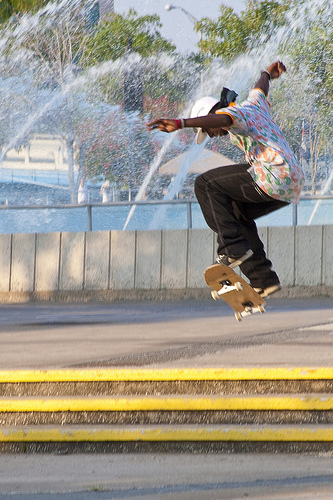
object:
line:
[0, 367, 332, 385]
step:
[0, 365, 333, 398]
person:
[143, 62, 298, 296]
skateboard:
[202, 261, 268, 325]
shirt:
[216, 88, 307, 202]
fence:
[0, 192, 330, 234]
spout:
[118, 0, 332, 233]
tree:
[0, 0, 172, 203]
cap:
[186, 96, 219, 145]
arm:
[178, 112, 237, 133]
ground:
[0, 453, 332, 499]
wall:
[0, 224, 333, 303]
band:
[177, 117, 187, 131]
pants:
[192, 162, 280, 283]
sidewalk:
[0, 293, 333, 367]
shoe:
[212, 247, 253, 269]